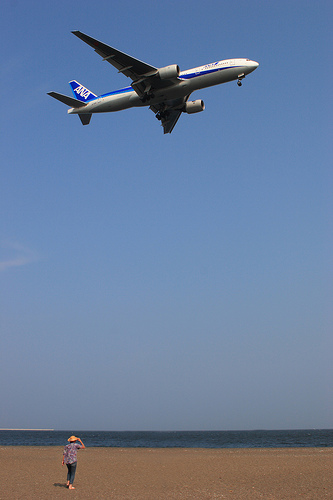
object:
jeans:
[66, 461, 77, 483]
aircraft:
[46, 29, 259, 134]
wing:
[148, 91, 192, 134]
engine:
[158, 64, 180, 80]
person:
[62, 435, 86, 489]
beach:
[0, 446, 333, 499]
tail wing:
[46, 90, 87, 108]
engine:
[186, 99, 206, 114]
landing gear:
[237, 79, 242, 87]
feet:
[66, 483, 75, 490]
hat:
[67, 436, 77, 442]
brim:
[67, 438, 76, 441]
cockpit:
[246, 58, 254, 65]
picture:
[0, 0, 333, 500]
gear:
[142, 93, 155, 103]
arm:
[76, 440, 86, 450]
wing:
[70, 29, 175, 92]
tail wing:
[78, 112, 92, 125]